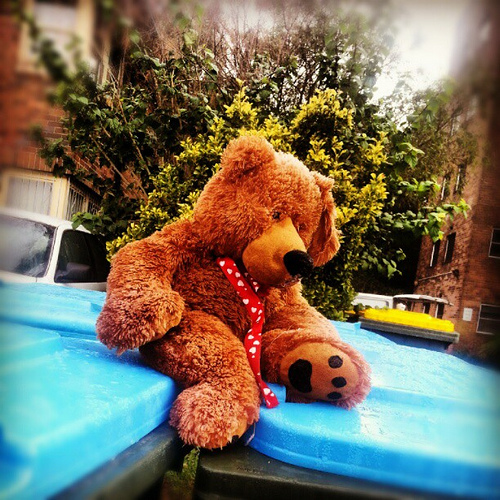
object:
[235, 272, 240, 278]
hearts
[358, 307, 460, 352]
garbage can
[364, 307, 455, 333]
lid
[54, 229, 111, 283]
window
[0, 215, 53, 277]
window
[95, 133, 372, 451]
bear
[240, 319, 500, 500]
bench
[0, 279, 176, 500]
bench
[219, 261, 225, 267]
heart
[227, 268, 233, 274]
heart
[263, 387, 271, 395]
heart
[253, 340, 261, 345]
heart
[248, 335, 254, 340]
heart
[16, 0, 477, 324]
leaves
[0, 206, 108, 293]
car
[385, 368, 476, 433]
table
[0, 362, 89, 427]
table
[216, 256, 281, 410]
neck collar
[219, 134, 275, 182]
ear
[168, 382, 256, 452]
foot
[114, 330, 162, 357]
paw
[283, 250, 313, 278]
nose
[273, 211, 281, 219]
eye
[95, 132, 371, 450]
fur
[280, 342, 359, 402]
footprint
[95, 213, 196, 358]
limb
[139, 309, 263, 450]
limb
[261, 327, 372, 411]
limb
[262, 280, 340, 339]
limb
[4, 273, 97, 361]
ground